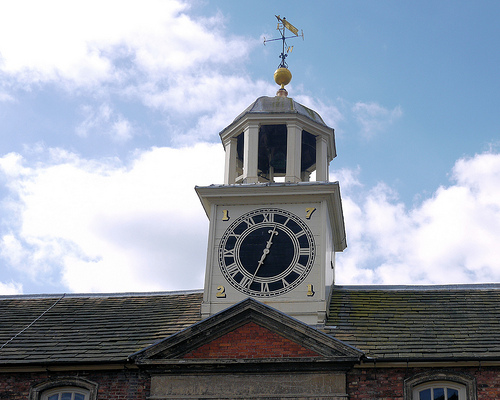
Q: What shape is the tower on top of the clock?
A: Round.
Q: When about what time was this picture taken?
A: 12:34.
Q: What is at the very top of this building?
A: Weathervane.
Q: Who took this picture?
A: Photographer.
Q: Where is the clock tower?
A: On the roof.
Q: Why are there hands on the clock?
A: To show time.